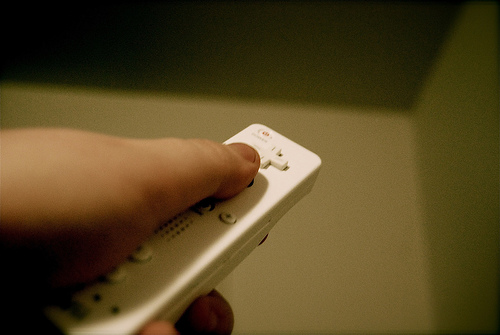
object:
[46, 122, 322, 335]
control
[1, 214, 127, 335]
shadow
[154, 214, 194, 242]
holes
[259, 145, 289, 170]
direction control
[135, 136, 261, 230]
finger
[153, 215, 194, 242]
openings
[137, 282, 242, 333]
fingers under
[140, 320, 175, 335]
finger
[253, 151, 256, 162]
dirt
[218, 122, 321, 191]
thumb remote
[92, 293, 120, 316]
light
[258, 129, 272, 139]
sign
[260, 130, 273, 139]
button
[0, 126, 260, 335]
hand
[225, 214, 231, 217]
screw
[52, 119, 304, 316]
cover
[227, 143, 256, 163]
nail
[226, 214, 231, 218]
plus sign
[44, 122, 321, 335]
controler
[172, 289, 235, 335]
finger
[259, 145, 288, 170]
button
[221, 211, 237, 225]
button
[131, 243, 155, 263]
button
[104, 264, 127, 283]
button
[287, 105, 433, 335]
light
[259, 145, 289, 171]
cross shape